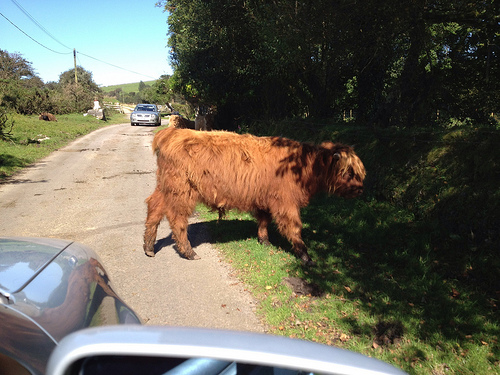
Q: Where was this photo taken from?
A: A car.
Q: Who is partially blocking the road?
A: A brown cow.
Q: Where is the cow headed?
A: Into the bushes.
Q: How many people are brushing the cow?
A: None.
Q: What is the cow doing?
A: Crossing the gray concrete road.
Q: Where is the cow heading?
A: Towards a shady patch of grass.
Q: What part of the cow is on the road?
A: A cow's back legs.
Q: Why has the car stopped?
A: Waiting for a brown cow crossing the road.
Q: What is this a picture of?
A: A brown cow crossing the road.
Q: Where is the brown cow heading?
A: The brown cow is crossing the road to get to the shade.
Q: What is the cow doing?
A: Crossing the road ?.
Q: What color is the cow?
A: Brown.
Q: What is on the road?
A: Silver cars.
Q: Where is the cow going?
A: Forest.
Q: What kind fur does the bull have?
A: Shaggy.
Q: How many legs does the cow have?
A: Four.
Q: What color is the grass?
A: Green.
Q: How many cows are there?
A: One.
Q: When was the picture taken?
A: Daytime.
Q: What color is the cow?
A: Brown.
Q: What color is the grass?
A: Green.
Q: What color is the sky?
A: Blue.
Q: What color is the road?
A: Gray.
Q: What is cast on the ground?
A: Shadows.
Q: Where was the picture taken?
A: A country road.